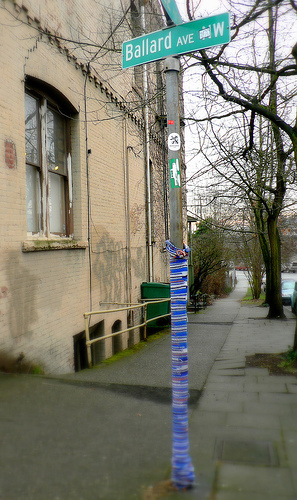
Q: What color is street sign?
A: Green.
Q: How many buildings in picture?
A: One.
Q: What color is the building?
A: Beige.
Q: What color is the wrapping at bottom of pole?
A: Blue.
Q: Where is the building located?
A: Ballard AVE NW.